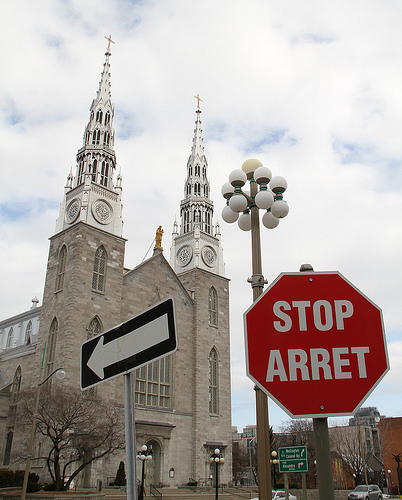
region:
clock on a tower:
[55, 197, 114, 219]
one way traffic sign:
[58, 325, 175, 386]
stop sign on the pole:
[235, 248, 390, 430]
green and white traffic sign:
[271, 436, 318, 481]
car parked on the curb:
[348, 468, 386, 497]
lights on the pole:
[203, 446, 225, 466]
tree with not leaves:
[16, 378, 107, 487]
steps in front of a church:
[152, 471, 260, 498]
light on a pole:
[51, 364, 68, 386]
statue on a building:
[150, 223, 167, 260]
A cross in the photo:
[81, 24, 140, 58]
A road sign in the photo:
[79, 299, 188, 386]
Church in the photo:
[54, 170, 235, 366]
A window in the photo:
[206, 283, 221, 330]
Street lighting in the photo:
[221, 167, 300, 243]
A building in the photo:
[163, 362, 222, 449]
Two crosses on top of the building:
[91, 33, 223, 158]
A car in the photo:
[349, 474, 388, 496]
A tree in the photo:
[52, 398, 103, 472]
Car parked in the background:
[347, 473, 382, 498]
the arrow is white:
[60, 321, 185, 397]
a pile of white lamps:
[193, 144, 292, 239]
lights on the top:
[208, 143, 303, 249]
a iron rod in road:
[100, 380, 145, 498]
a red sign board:
[231, 248, 400, 407]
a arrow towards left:
[55, 311, 207, 420]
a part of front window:
[116, 333, 184, 422]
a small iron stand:
[205, 431, 238, 493]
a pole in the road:
[192, 425, 235, 498]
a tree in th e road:
[20, 386, 129, 496]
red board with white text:
[243, 271, 390, 427]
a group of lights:
[221, 145, 295, 243]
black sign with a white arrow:
[70, 295, 180, 397]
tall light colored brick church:
[9, 28, 232, 483]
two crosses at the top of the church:
[87, 24, 220, 119]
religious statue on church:
[147, 219, 170, 257]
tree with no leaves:
[7, 375, 131, 491]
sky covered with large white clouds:
[247, 23, 364, 138]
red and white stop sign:
[234, 260, 386, 427]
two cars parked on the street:
[257, 479, 399, 496]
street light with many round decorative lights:
[214, 152, 296, 496]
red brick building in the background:
[261, 413, 401, 489]